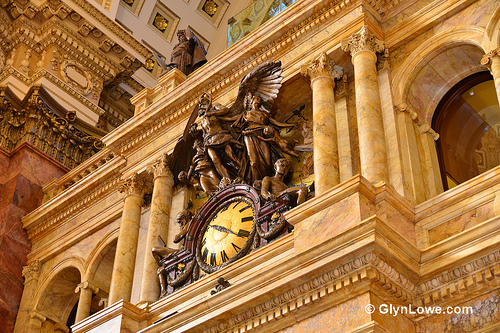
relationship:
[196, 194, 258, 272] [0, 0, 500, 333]
clock on building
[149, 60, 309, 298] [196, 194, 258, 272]
statue on clock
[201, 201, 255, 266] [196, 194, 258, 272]
roman numerals on clock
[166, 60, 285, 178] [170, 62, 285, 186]
statue has wings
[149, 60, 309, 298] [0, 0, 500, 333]
statue on building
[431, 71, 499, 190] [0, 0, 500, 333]
window in building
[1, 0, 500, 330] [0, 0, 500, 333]
gold in building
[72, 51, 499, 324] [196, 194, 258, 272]
pillars around clock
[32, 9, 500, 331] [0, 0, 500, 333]
arches in building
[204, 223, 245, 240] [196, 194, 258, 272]
hands on clock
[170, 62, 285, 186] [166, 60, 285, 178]
wings on statue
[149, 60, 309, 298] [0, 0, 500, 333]
statue in building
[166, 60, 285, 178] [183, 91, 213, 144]
statue has a sword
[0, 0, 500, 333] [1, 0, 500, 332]
building made of stone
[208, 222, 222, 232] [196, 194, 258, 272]
minute hand on clock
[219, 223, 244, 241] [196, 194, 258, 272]
hour hand on clock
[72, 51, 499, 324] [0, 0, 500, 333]
pillars in building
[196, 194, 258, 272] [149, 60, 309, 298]
clock under statue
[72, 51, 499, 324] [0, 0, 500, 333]
pillars inside building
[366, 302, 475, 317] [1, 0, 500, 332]
water mark on picture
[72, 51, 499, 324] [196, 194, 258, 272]
pillars near clock